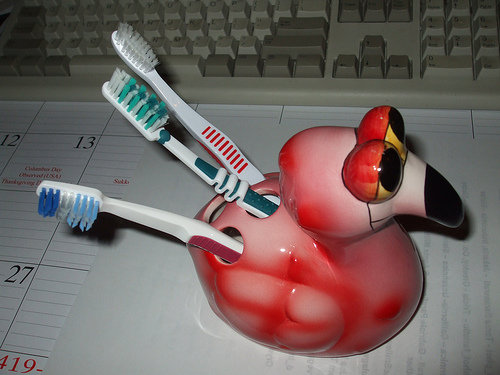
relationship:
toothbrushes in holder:
[32, 21, 279, 267] [193, 102, 469, 363]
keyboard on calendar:
[4, 4, 499, 109] [1, 101, 499, 375]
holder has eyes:
[193, 102, 469, 363] [339, 102, 411, 205]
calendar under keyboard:
[1, 101, 499, 375] [4, 4, 499, 109]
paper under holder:
[71, 116, 497, 374] [193, 102, 469, 363]